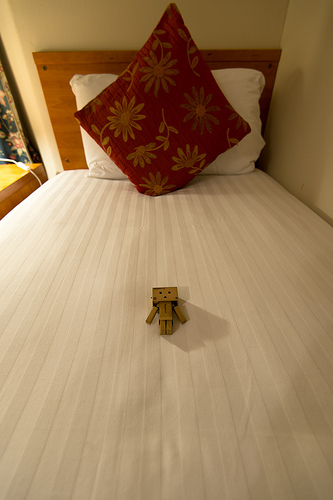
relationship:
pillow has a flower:
[73, 4, 253, 198] [178, 82, 221, 136]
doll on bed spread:
[147, 281, 190, 341] [0, 168, 333, 499]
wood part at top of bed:
[30, 40, 282, 176] [2, 48, 331, 497]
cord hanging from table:
[1, 157, 43, 187] [1, 157, 46, 219]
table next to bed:
[1, 157, 46, 219] [2, 48, 331, 497]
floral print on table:
[1, 65, 42, 168] [1, 157, 46, 219]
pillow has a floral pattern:
[73, 4, 253, 198] [178, 82, 221, 136]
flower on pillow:
[178, 82, 221, 136] [73, 4, 253, 198]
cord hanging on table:
[1, 157, 43, 187] [1, 157, 46, 219]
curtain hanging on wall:
[1, 65, 42, 168] [2, 1, 333, 225]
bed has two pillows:
[2, 48, 331, 497] [65, 4, 268, 197]